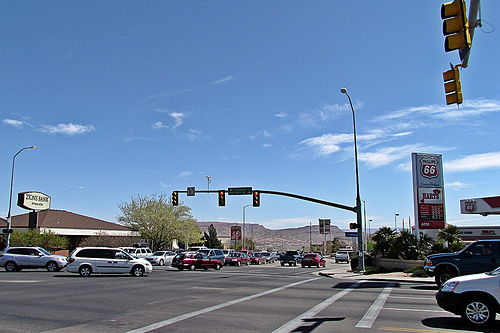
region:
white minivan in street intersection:
[65, 243, 150, 280]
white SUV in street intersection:
[0, 244, 63, 271]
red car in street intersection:
[172, 248, 224, 273]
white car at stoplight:
[434, 261, 499, 326]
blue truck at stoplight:
[420, 233, 495, 285]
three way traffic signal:
[169, 188, 179, 207]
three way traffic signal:
[214, 187, 226, 205]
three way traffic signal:
[249, 186, 261, 209]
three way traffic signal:
[435, 62, 462, 106]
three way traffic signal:
[438, 0, 472, 62]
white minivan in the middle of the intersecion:
[67, 245, 152, 278]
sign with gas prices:
[412, 151, 447, 231]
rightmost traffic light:
[251, 189, 259, 204]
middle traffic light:
[217, 188, 226, 205]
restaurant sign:
[18, 190, 53, 210]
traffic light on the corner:
[338, 83, 366, 207]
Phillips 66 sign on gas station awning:
[462, 197, 477, 216]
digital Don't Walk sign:
[348, 221, 357, 230]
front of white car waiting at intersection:
[437, 266, 499, 323]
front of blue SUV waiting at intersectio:
[421, 237, 496, 282]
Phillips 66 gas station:
[414, 151, 496, 248]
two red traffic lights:
[217, 187, 259, 209]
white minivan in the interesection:
[67, 246, 149, 273]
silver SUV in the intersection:
[2, 246, 64, 271]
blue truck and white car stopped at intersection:
[430, 237, 499, 332]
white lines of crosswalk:
[121, 277, 363, 328]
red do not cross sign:
[349, 222, 358, 229]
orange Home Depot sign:
[230, 225, 241, 242]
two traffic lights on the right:
[438, 1, 485, 115]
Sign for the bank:
[18, 191, 51, 211]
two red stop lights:
[216, 188, 262, 208]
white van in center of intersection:
[65, 246, 153, 278]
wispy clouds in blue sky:
[4, 73, 499, 176]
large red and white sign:
[409, 149, 450, 238]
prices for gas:
[418, 203, 445, 222]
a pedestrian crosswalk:
[136, 274, 367, 331]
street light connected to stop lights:
[337, 84, 367, 269]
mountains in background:
[198, 220, 363, 255]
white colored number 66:
[419, 162, 439, 177]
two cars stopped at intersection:
[421, 236, 498, 323]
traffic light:
[132, 143, 293, 253]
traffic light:
[143, 164, 265, 224]